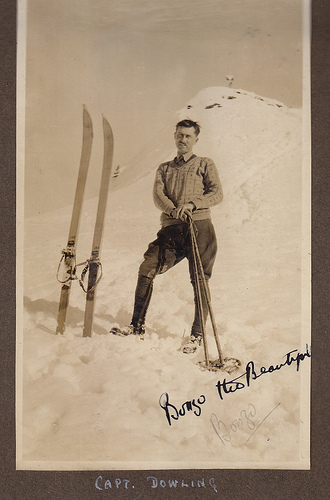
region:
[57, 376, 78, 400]
white snow on ground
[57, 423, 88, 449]
white snow on ground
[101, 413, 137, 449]
white snow on ground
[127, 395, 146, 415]
white snow on ground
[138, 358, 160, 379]
white snow on ground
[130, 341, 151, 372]
white snow on ground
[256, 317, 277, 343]
white snow on ground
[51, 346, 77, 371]
white snow on ground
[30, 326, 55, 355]
white snow on ground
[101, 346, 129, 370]
white snow on ground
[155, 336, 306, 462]
pre-printed and hand-signed signatures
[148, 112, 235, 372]
skier holding ski poles to the side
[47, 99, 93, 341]
upright ski poles stuck into snow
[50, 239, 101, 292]
belted loops and attachments on skis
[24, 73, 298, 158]
mountain top with steep slope above skier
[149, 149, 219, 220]
shirt and tie under sweater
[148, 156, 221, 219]
sweater design of squares within squares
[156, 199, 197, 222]
one hand over the other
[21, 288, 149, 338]
shadow behind skis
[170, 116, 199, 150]
mustache over open mouth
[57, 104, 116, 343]
pair of skiis standing vertically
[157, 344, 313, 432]
person's signature on the photo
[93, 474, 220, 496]
white writing under the photo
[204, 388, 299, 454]
person's signature in gray writing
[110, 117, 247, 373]
skiier standing in the snow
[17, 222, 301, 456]
fresh snow on the ground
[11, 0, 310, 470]
an old sephia colored photograph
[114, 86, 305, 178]
top of the skii hill in the background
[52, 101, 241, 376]
man with his skiis posting for a photo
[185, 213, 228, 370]
skii poles in the man's hands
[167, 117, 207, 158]
head of man in photo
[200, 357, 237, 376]
ski tips in the snow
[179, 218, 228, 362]
large ski poles in hands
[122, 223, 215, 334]
black ski pants on man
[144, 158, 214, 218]
white sweater on man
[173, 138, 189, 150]
mustache on face of man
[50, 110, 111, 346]
skis in the ground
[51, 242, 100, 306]
spots for ski boots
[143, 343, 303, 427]
black writing on picture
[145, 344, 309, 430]
black signature on picture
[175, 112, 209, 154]
head of a person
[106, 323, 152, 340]
leg of a person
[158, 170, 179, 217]
arm of a person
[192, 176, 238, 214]
arm of a person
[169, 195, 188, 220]
hand of a person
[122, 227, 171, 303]
leg of a person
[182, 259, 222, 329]
leg of a person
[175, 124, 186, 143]
eye of a person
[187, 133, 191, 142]
eye of a person